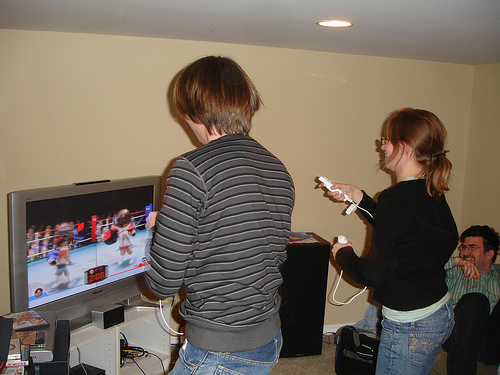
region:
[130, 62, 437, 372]
two people with Wii controllers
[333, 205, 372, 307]
white cords on controllers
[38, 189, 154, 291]
boxing game on television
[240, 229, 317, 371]
black speakers next to television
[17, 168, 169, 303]
grey frame on television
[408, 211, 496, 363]
man sitting next to woman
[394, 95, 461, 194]
woman has brown hair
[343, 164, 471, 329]
woman has black shirt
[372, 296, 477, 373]
woman has blue jeans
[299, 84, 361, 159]
tan wall behind woman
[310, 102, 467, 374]
a girl is holding a wii controller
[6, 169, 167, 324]
a video game is playing on the tv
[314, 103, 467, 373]
girl has her hair tied in a pony tail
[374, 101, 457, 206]
girl is wearing glasses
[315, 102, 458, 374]
girl wears blue jeans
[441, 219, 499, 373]
man is sitting down and laughing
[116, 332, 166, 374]
cables on a shelf under a tv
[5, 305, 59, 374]
computer games are piled up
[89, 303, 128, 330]
a speaker is in front of a tv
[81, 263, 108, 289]
a red digital timer is displayed on the tv screen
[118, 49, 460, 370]
two people playing video game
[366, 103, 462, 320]
woman wearing black sweater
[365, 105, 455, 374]
woman wearing blue jeans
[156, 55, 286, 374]
man wearing striped long sleeved shirt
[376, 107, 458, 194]
woman with light brown hair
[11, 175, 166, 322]
video game on large TV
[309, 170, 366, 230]
one hand holding Wii controller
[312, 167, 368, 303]
woman's hands holding video game controller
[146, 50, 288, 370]
back of brown haired man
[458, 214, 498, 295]
man with glasses smiling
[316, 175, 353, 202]
A white game controller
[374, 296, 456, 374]
A pair of light colored blue jeans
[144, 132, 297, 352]
A grey stripped shirt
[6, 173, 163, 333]
A silver flat screen tv.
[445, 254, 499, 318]
A green striped shirt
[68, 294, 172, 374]
A white shelf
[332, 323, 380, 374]
A black bag sitting on floor.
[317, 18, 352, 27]
A white light on ceiling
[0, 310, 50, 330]
A video game case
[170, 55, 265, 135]
Brown short hair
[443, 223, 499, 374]
man sitting and laughing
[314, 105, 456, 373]
woman holding Nintendo Wii controllers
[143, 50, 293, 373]
man playing Nintendo Wii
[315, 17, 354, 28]
recessed lighting in ceiling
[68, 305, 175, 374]
white TV stand on floor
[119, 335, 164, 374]
cords on shelf of white TV stand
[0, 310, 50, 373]
randomly stacked DVDs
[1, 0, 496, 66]
white ceiling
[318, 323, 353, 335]
white baseboard on wall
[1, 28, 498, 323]
beige walls